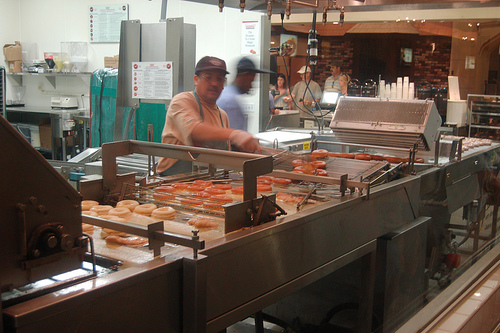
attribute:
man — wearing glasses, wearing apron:
[200, 75, 228, 88]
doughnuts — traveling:
[310, 146, 325, 157]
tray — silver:
[271, 147, 382, 186]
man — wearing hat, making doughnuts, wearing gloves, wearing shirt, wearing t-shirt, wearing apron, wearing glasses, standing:
[159, 54, 270, 181]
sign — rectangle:
[87, 7, 127, 43]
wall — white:
[4, 2, 256, 128]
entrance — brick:
[309, 32, 448, 107]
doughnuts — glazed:
[158, 181, 245, 210]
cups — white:
[377, 71, 416, 104]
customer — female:
[270, 73, 291, 107]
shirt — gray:
[290, 82, 319, 102]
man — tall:
[321, 59, 352, 97]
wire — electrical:
[281, 56, 331, 127]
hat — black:
[196, 56, 229, 72]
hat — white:
[298, 66, 313, 77]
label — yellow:
[302, 144, 318, 155]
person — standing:
[297, 64, 320, 105]